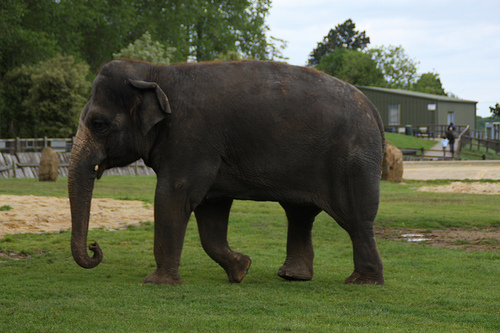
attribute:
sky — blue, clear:
[187, 2, 499, 117]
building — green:
[348, 70, 485, 151]